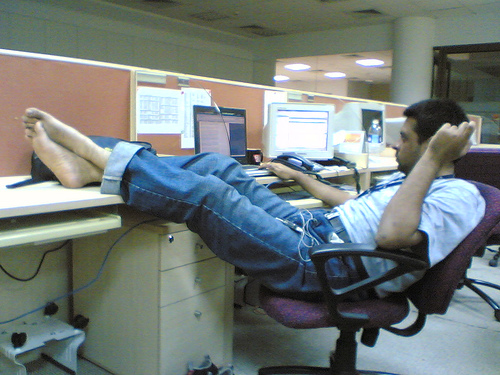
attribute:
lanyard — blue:
[354, 173, 455, 200]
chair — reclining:
[257, 181, 497, 373]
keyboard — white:
[240, 164, 272, 175]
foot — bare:
[24, 123, 95, 187]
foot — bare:
[22, 107, 99, 163]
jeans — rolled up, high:
[100, 141, 369, 297]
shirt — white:
[332, 169, 484, 297]